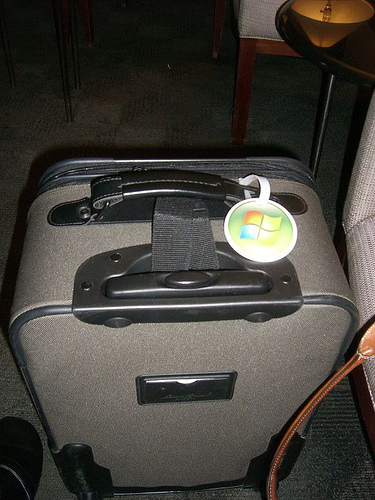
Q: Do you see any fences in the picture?
A: No, there are no fences.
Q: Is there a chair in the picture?
A: Yes, there is a chair.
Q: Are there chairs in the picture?
A: Yes, there is a chair.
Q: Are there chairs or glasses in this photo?
A: Yes, there is a chair.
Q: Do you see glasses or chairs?
A: Yes, there is a chair.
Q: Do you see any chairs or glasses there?
A: Yes, there is a chair.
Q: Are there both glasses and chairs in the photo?
A: No, there is a chair but no glasses.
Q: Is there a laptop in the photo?
A: No, there are no laptops.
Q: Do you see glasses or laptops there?
A: No, there are no laptops or glasses.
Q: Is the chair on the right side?
A: Yes, the chair is on the right of the image.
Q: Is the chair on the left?
A: No, the chair is on the right of the image.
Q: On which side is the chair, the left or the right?
A: The chair is on the right of the image.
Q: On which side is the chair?
A: The chair is on the right of the image.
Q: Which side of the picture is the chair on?
A: The chair is on the right of the image.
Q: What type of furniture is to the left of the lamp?
A: The piece of furniture is a chair.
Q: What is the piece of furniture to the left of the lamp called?
A: The piece of furniture is a chair.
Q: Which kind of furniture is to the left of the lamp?
A: The piece of furniture is a chair.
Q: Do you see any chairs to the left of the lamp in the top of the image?
A: Yes, there is a chair to the left of the lamp.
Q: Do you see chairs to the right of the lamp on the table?
A: No, the chair is to the left of the lamp.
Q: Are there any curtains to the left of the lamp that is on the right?
A: No, there is a chair to the left of the lamp.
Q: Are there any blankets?
A: No, there are no blankets.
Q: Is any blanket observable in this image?
A: No, there are no blankets.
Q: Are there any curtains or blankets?
A: No, there are no blankets or curtains.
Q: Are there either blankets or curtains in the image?
A: No, there are no blankets or curtains.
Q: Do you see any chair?
A: Yes, there is a chair.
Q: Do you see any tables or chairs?
A: Yes, there is a chair.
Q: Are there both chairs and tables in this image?
A: Yes, there are both a chair and a table.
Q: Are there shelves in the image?
A: No, there are no shelves.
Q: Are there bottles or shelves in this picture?
A: No, there are no shelves or bottles.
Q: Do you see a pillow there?
A: No, there are no pillows.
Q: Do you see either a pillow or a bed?
A: No, there are no pillows or beds.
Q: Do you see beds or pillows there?
A: No, there are no pillows or beds.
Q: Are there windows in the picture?
A: Yes, there are windows.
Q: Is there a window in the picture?
A: Yes, there are windows.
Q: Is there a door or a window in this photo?
A: Yes, there are windows.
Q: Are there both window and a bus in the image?
A: No, there are windows but no buses.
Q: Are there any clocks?
A: No, there are no clocks.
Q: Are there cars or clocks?
A: No, there are no clocks or cars.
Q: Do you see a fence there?
A: No, there are no fences.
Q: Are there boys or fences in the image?
A: No, there are no fences or boys.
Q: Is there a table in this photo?
A: Yes, there is a table.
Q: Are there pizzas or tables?
A: Yes, there is a table.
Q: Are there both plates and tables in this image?
A: No, there is a table but no plates.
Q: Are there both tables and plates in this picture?
A: No, there is a table but no plates.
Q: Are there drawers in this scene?
A: No, there are no drawers.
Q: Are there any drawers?
A: No, there are no drawers.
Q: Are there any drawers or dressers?
A: No, there are no drawers or dressers.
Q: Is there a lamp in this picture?
A: Yes, there is a lamp.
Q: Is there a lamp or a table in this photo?
A: Yes, there is a lamp.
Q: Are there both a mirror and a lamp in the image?
A: No, there is a lamp but no mirrors.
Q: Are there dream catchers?
A: No, there are no dream catchers.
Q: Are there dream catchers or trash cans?
A: No, there are no dream catchers or trash cans.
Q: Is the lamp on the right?
A: Yes, the lamp is on the right of the image.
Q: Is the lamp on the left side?
A: No, the lamp is on the right of the image.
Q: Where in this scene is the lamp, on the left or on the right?
A: The lamp is on the right of the image.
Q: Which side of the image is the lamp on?
A: The lamp is on the right of the image.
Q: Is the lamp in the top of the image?
A: Yes, the lamp is in the top of the image.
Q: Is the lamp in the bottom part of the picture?
A: No, the lamp is in the top of the image.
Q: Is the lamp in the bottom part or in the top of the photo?
A: The lamp is in the top of the image.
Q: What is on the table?
A: The lamp is on the table.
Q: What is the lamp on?
A: The lamp is on the table.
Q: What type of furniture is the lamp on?
A: The lamp is on the table.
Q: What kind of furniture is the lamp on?
A: The lamp is on the table.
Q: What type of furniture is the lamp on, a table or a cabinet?
A: The lamp is on a table.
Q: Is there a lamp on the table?
A: Yes, there is a lamp on the table.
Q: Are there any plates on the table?
A: No, there is a lamp on the table.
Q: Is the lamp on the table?
A: Yes, the lamp is on the table.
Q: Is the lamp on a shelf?
A: No, the lamp is on the table.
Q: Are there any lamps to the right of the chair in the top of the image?
A: Yes, there is a lamp to the right of the chair.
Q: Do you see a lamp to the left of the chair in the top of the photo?
A: No, the lamp is to the right of the chair.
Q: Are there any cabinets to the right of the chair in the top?
A: No, there is a lamp to the right of the chair.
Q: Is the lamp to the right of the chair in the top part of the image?
A: Yes, the lamp is to the right of the chair.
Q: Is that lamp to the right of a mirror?
A: No, the lamp is to the right of the chair.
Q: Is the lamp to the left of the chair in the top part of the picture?
A: No, the lamp is to the right of the chair.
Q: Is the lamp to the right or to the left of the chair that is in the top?
A: The lamp is to the right of the chair.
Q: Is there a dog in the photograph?
A: No, there are no dogs.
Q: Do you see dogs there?
A: No, there are no dogs.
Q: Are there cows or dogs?
A: No, there are no dogs or cows.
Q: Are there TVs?
A: No, there are no tvs.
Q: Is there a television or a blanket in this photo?
A: No, there are no televisions or blankets.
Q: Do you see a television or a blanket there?
A: No, there are no televisions or blankets.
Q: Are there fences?
A: No, there are no fences.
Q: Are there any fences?
A: No, there are no fences.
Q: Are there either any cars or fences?
A: No, there are no fences or cars.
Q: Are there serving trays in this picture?
A: No, there are no serving trays.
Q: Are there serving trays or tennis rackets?
A: No, there are no serving trays or tennis rackets.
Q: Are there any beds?
A: No, there are no beds.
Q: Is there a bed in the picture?
A: No, there are no beds.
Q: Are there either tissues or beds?
A: No, there are no beds or tissues.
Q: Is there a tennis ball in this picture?
A: No, there are no tennis balls.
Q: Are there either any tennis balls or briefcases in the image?
A: No, there are no tennis balls or briefcases.